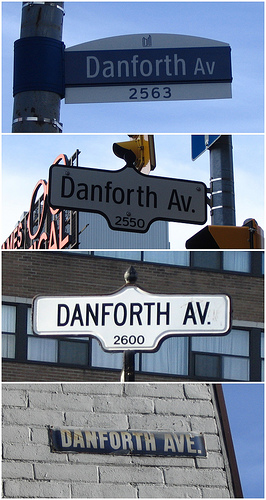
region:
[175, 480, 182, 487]
part of a wall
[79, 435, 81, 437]
edge of a post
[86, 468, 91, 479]
part of a brick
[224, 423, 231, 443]
side of a wall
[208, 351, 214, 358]
part of a window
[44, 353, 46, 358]
edge of a window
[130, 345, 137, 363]
part of a post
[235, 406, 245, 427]
part of the sky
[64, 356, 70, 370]
edge of a window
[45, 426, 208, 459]
the street sign attached to the brick wall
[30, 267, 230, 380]
a fancy street sign attached to the pole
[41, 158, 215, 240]
another street sign, another pole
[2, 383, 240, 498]
the brick wall of the building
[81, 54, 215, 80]
the name of the street on the sign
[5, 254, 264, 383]
a building behind the sign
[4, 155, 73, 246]
the sign with the name of the business on it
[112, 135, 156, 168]
part of the traffic light with the green light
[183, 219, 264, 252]
the traffic light for the pedestrians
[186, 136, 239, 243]
the pole all the lights are attached too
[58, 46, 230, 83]
The sign is blue and white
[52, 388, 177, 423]
The building is made of brick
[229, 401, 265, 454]
The sky is blue and clear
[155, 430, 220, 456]
The word ave is white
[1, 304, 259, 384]
The building has many windows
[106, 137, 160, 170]
The traffic signal is yellow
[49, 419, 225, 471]
The sign says Danforth Ave.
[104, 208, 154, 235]
The sign has numbers 2550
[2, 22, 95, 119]
The sign is on a pole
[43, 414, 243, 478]
The sign is on a building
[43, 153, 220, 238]
danforth ave street sign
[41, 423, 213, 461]
danforth ave street sign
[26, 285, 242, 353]
danforth ave street sign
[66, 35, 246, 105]
danforth ave street sign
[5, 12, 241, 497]
image of four danforth ave street signs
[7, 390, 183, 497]
white brick wall with sign on it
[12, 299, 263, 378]
row of windows behind sign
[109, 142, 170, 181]
yellow stop light above sign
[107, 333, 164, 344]
number 2600 on white sign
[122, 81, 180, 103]
number 2563 on street sign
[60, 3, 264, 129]
blue of daytime sky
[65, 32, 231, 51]
curved top of sign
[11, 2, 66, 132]
pole with three braces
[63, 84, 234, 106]
number on white surface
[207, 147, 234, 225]
three braces on pole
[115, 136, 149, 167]
side of yellow traffic light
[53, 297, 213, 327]
black letters on white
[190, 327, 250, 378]
white curtain in window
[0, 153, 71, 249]
red numbers on sign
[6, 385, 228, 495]
brick wall painted white